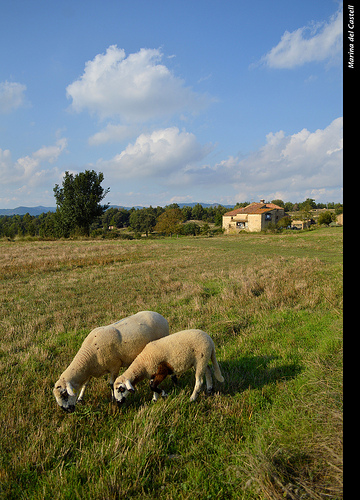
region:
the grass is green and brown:
[301, 462, 315, 493]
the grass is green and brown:
[299, 448, 311, 476]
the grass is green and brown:
[279, 456, 294, 484]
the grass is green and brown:
[288, 476, 299, 498]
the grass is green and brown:
[274, 454, 287, 486]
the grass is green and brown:
[255, 467, 269, 493]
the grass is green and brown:
[276, 486, 281, 496]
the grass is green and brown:
[293, 455, 306, 485]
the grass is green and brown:
[283, 467, 295, 490]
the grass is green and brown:
[270, 472, 288, 490]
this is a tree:
[54, 173, 118, 231]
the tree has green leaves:
[65, 184, 84, 206]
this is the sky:
[2, 5, 96, 56]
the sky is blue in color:
[29, 13, 61, 40]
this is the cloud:
[92, 65, 169, 114]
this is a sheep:
[128, 344, 219, 369]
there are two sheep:
[51, 317, 218, 396]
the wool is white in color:
[117, 321, 144, 335]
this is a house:
[237, 199, 267, 232]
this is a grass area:
[232, 332, 287, 372]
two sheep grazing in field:
[43, 297, 238, 427]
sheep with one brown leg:
[111, 328, 230, 414]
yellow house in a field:
[215, 177, 336, 311]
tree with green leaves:
[49, 157, 114, 254]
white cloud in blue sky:
[77, 44, 218, 163]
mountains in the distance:
[1, 200, 56, 218]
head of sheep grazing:
[111, 371, 140, 408]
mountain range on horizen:
[113, 192, 229, 214]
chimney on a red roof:
[254, 194, 277, 209]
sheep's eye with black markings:
[115, 384, 127, 395]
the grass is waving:
[212, 448, 273, 488]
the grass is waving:
[223, 479, 241, 487]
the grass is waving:
[219, 401, 266, 459]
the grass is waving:
[233, 466, 281, 482]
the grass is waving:
[228, 435, 268, 482]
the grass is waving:
[227, 430, 259, 450]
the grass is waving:
[236, 430, 282, 452]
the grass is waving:
[238, 399, 278, 446]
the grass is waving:
[240, 415, 267, 434]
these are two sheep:
[45, 298, 224, 412]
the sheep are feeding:
[44, 304, 226, 444]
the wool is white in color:
[106, 321, 138, 354]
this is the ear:
[64, 380, 75, 394]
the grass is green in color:
[107, 419, 226, 484]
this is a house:
[225, 197, 281, 236]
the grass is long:
[234, 423, 302, 492]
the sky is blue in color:
[184, 4, 238, 52]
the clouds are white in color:
[87, 60, 162, 112]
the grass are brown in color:
[205, 254, 297, 305]